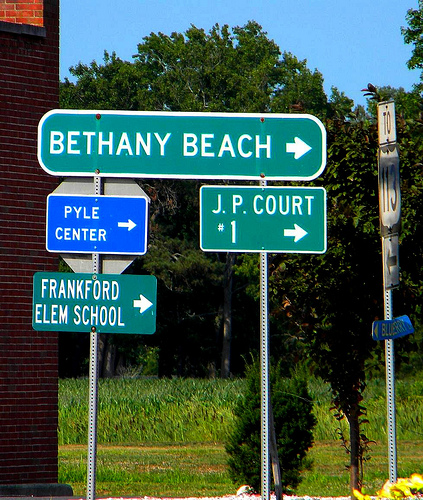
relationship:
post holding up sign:
[256, 252, 271, 498] [36, 107, 328, 182]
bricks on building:
[9, 79, 31, 92] [0, 1, 74, 496]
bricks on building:
[8, 98, 29, 105] [0, 1, 74, 496]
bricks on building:
[8, 146, 32, 161] [0, 1, 74, 496]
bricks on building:
[15, 172, 40, 188] [0, 1, 74, 496]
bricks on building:
[9, 186, 36, 208] [0, 1, 74, 496]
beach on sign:
[183, 131, 271, 159] [37, 105, 326, 182]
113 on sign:
[376, 160, 398, 215] [366, 92, 404, 233]